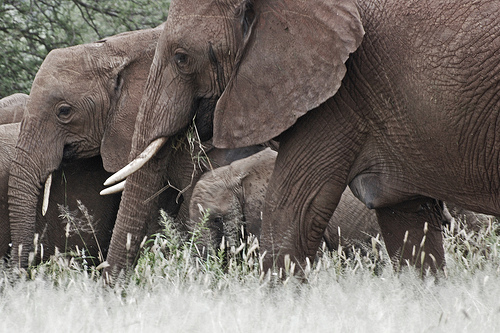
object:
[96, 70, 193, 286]
trunk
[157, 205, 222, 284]
grass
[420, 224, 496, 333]
hay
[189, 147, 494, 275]
baby elephant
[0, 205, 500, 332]
field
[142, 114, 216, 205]
grass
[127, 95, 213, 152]
mouth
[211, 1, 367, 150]
ear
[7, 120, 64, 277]
trunk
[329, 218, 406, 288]
fern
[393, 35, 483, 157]
skin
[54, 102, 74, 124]
eye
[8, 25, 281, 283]
elephant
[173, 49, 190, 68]
eye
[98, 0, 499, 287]
mom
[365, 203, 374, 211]
nipple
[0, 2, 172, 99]
trees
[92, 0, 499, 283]
elephant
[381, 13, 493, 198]
skin elephant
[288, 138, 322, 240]
skin elephant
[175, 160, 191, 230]
skin elephant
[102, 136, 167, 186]
tusks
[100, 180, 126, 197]
tusks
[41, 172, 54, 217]
tusks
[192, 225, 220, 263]
trunk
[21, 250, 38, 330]
plants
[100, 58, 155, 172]
ear